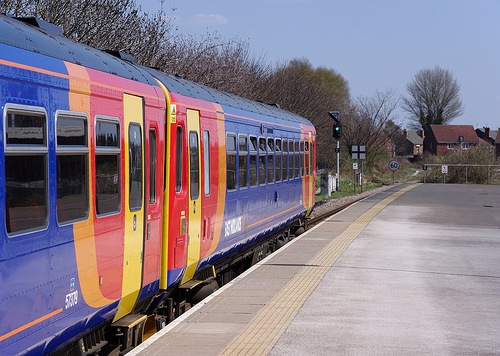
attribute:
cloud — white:
[183, 10, 225, 27]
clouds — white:
[171, 8, 274, 60]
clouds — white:
[140, 3, 498, 141]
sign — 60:
[386, 159, 399, 172]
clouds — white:
[301, 21, 412, 91]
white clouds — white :
[352, 57, 384, 90]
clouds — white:
[339, 19, 409, 66]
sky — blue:
[218, 10, 473, 53]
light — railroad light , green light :
[326, 110, 344, 192]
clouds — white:
[160, 11, 228, 29]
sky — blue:
[116, 0, 498, 132]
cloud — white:
[155, 11, 179, 26]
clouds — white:
[161, 5, 238, 33]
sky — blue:
[297, 17, 355, 41]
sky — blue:
[250, 11, 488, 73]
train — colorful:
[4, 10, 319, 352]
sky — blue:
[289, 14, 409, 38]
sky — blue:
[324, 2, 414, 69]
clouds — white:
[219, 10, 309, 51]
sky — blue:
[256, 11, 392, 48]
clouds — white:
[246, 13, 366, 69]